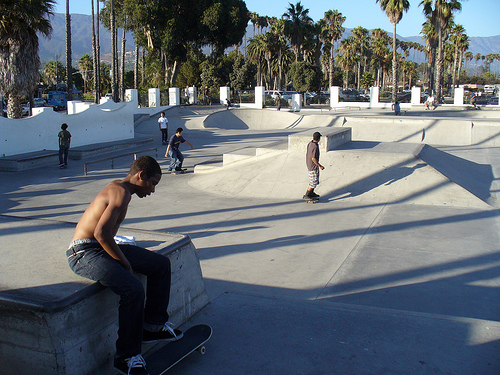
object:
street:
[1, 201, 499, 374]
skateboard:
[121, 323, 214, 375]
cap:
[312, 131, 322, 140]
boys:
[57, 123, 73, 168]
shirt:
[157, 117, 168, 130]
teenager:
[164, 127, 194, 176]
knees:
[171, 156, 179, 162]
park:
[0, 74, 500, 375]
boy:
[64, 154, 184, 375]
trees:
[374, 0, 412, 117]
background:
[0, 0, 500, 208]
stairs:
[193, 125, 353, 174]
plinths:
[0, 84, 500, 158]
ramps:
[186, 143, 495, 210]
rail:
[82, 147, 160, 176]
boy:
[302, 131, 326, 204]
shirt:
[306, 141, 321, 172]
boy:
[157, 111, 169, 145]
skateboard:
[162, 140, 173, 146]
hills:
[2, 6, 500, 92]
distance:
[3, 0, 499, 86]